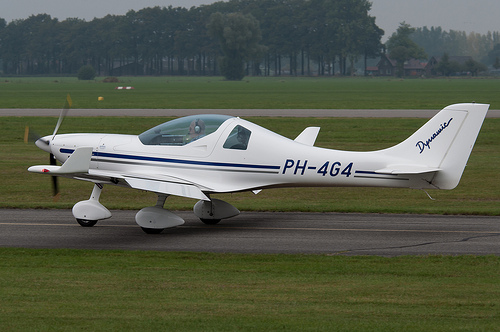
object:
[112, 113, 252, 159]
cockpit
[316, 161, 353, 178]
number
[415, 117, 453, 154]
text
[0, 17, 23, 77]
trees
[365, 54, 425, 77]
cabin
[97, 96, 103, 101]
object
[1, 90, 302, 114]
ground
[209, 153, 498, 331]
airport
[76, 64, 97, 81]
bush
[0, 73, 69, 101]
grass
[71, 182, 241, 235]
landing gear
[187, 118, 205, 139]
pilot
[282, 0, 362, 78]
trees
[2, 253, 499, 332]
grass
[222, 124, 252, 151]
window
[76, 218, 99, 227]
wheel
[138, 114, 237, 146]
window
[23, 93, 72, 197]
propeller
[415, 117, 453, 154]
name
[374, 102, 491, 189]
tail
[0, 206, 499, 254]
runway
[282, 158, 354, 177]
ph-4g4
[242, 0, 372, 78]
tree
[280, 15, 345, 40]
leaves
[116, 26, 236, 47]
leaves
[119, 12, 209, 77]
tree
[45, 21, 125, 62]
tree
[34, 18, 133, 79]
leaves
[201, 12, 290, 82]
tree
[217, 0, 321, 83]
leaves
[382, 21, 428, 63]
leaves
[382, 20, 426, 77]
tree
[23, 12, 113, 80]
tree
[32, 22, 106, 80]
leaves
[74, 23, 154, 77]
leaves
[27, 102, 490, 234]
airplane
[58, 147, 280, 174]
stripes